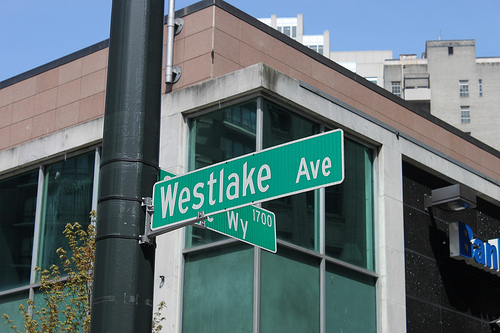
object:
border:
[162, 176, 179, 182]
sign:
[152, 128, 345, 254]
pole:
[92, 0, 168, 333]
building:
[168, 4, 491, 332]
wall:
[407, 186, 447, 332]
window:
[3, 145, 96, 296]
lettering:
[294, 156, 332, 183]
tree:
[21, 222, 93, 333]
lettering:
[158, 164, 271, 222]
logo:
[448, 221, 499, 276]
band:
[100, 157, 160, 171]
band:
[99, 195, 145, 202]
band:
[96, 234, 141, 242]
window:
[190, 100, 259, 170]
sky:
[309, 5, 494, 31]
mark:
[179, 79, 214, 94]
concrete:
[226, 61, 297, 97]